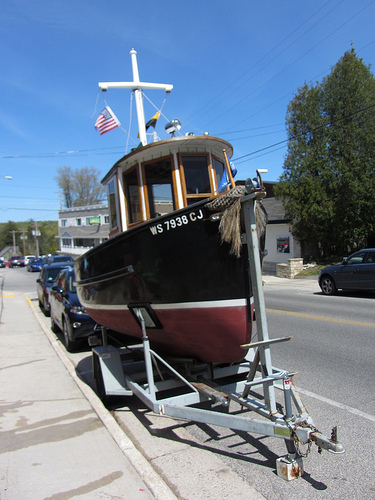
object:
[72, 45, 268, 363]
ship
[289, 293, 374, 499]
road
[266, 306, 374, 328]
line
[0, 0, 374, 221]
sky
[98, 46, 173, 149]
cross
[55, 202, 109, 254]
building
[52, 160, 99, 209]
brown trees